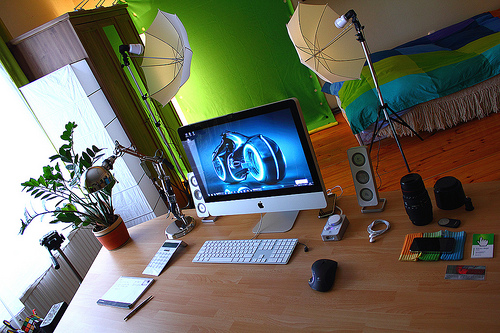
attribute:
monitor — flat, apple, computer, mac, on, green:
[172, 90, 334, 237]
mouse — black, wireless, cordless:
[302, 254, 338, 296]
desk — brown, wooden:
[41, 177, 499, 332]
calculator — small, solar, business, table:
[137, 232, 190, 280]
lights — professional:
[283, 3, 430, 177]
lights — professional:
[113, 7, 198, 206]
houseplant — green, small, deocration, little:
[11, 119, 137, 259]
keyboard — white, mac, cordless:
[187, 233, 301, 268]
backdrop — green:
[108, 1, 341, 156]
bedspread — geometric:
[317, 7, 500, 138]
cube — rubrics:
[19, 311, 43, 332]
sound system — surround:
[346, 140, 388, 217]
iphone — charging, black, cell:
[408, 234, 458, 256]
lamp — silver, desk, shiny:
[76, 133, 197, 241]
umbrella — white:
[283, 0, 372, 94]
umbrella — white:
[135, 6, 198, 111]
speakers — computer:
[343, 141, 389, 218]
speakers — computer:
[185, 169, 222, 226]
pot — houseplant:
[86, 208, 133, 251]